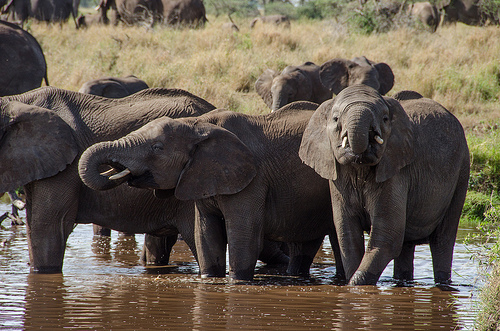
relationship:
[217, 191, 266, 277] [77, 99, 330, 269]
leg of elephant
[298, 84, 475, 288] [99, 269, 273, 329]
elephant in water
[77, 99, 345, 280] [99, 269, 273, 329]
elephant in water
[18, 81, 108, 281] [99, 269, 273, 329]
elephant in water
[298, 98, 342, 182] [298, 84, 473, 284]
ear on elephant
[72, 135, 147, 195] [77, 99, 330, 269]
trunk on elephant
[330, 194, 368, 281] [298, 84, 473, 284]
leg of elephant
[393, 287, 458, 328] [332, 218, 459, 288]
reflection of legs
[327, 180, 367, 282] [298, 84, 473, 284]
leg of elephant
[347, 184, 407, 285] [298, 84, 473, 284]
leg of elephant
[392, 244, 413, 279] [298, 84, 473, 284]
leg of elephant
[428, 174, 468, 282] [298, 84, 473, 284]
leg of elephant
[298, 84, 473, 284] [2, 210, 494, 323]
elephant inside water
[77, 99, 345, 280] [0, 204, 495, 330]
elephant in lake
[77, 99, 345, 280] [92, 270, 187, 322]
elephant in water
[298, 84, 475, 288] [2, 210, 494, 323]
elephant near water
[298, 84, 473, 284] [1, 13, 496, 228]
elephant near grass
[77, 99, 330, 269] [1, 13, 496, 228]
elephant near grass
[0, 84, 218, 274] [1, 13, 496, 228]
elephant near grass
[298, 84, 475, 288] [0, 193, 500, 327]
elephant in lake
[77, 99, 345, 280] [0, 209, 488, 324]
elephant in lake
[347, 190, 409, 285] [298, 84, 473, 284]
leg is on elephant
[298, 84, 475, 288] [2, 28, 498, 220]
elephant is on grass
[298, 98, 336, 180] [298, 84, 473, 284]
ear is on elephant